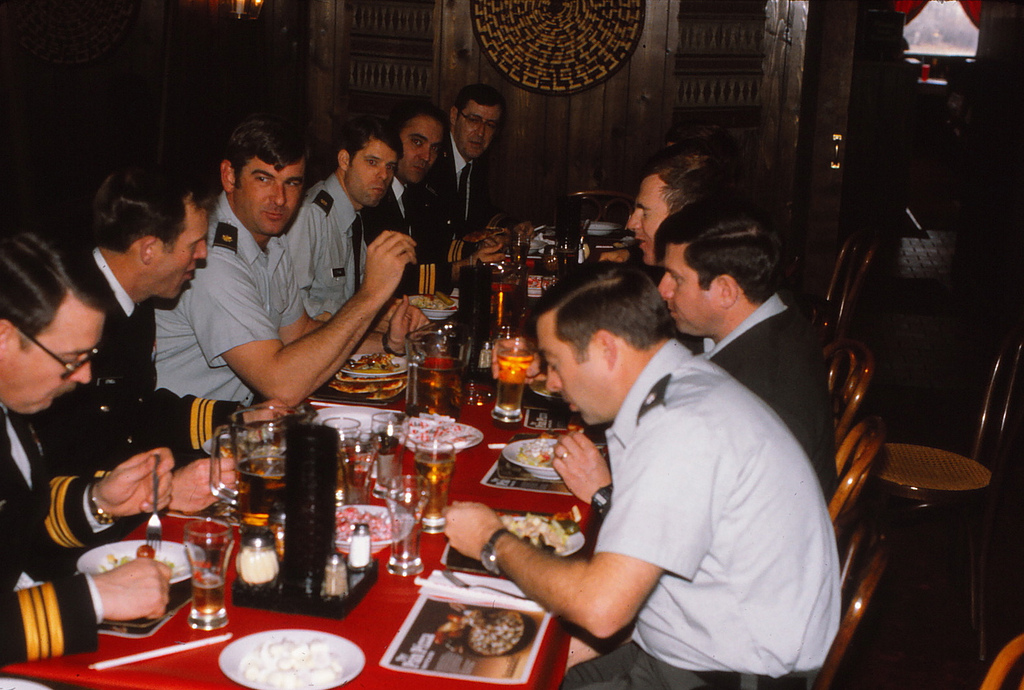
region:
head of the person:
[538, 298, 618, 398]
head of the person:
[662, 205, 780, 330]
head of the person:
[626, 161, 703, 251]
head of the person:
[16, 274, 94, 411]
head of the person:
[117, 171, 210, 295]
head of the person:
[378, 86, 430, 181]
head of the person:
[124, 173, 216, 304]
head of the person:
[431, 104, 508, 140]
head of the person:
[334, 142, 433, 225]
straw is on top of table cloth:
[87, 630, 228, 672]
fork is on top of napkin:
[441, 567, 524, 600]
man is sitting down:
[441, 258, 840, 685]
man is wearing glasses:
[2, 229, 176, 656]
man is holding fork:
[0, 226, 181, 663]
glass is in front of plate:
[185, 507, 234, 632]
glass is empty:
[383, 472, 426, 578]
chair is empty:
[874, 314, 1018, 665]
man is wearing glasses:
[427, 83, 533, 255]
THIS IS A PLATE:
[201, 611, 378, 684]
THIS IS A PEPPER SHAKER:
[310, 545, 358, 612]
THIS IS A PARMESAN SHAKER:
[219, 520, 286, 593]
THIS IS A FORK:
[137, 446, 172, 545]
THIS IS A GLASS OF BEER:
[175, 512, 243, 626]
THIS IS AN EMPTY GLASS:
[355, 454, 432, 590]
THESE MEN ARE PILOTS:
[0, 80, 866, 685]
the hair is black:
[544, 259, 674, 348]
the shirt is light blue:
[603, 391, 841, 655]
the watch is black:
[474, 530, 504, 584]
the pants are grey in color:
[571, 642, 699, 687]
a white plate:
[220, 623, 363, 687]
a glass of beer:
[405, 440, 467, 513]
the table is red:
[108, 228, 650, 675]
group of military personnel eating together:
[0, 69, 855, 686]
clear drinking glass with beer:
[185, 520, 239, 632]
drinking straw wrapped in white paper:
[84, 628, 241, 686]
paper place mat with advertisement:
[375, 568, 563, 686]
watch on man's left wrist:
[472, 520, 515, 579]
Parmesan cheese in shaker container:
[220, 532, 282, 589]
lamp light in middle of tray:
[282, 423, 344, 592]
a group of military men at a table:
[0, 82, 854, 665]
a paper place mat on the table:
[381, 511, 584, 683]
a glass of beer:
[412, 433, 457, 526]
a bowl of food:
[336, 342, 406, 378]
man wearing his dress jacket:
[23, 173, 290, 468]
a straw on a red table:
[90, 626, 231, 672]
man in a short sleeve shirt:
[433, 263, 842, 687]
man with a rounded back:
[444, 266, 844, 687]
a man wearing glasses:
[1, 230, 164, 677]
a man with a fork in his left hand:
[0, 228, 172, 669]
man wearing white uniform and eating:
[194, 147, 303, 401]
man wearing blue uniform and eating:
[637, 195, 790, 372]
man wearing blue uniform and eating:
[86, 188, 203, 438]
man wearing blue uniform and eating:
[462, 69, 520, 203]